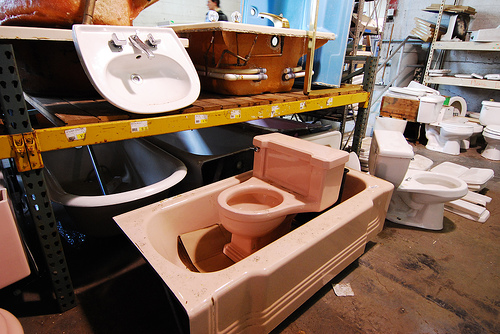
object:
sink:
[226, 186, 285, 212]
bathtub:
[244, 117, 329, 138]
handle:
[249, 146, 261, 153]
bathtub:
[40, 139, 187, 206]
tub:
[215, 177, 292, 239]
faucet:
[127, 30, 157, 60]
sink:
[103, 53, 203, 114]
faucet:
[257, 12, 288, 29]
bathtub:
[141, 126, 258, 185]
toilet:
[367, 130, 470, 232]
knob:
[147, 32, 162, 46]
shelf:
[0, 86, 372, 170]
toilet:
[479, 101, 500, 161]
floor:
[381, 244, 466, 325]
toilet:
[215, 132, 352, 263]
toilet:
[416, 95, 476, 155]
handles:
[112, 33, 126, 46]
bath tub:
[113, 131, 398, 334]